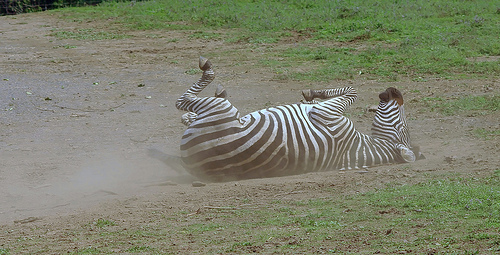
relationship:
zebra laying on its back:
[176, 58, 426, 181] [195, 164, 373, 183]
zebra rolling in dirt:
[176, 58, 426, 181] [1, 1, 498, 254]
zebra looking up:
[176, 58, 426, 181] [0, 0, 497, 96]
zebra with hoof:
[176, 58, 426, 181] [199, 57, 213, 71]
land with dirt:
[0, 2, 498, 254] [1, 1, 498, 254]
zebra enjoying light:
[176, 58, 426, 181] [3, 3, 496, 253]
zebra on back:
[176, 58, 426, 181] [195, 164, 373, 183]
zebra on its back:
[176, 58, 426, 181] [195, 164, 373, 183]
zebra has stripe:
[176, 58, 426, 181] [297, 104, 327, 172]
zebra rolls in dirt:
[176, 58, 426, 181] [1, 1, 498, 254]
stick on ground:
[179, 205, 237, 218] [0, 2, 498, 254]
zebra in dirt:
[176, 58, 426, 181] [1, 1, 498, 254]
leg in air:
[314, 88, 360, 115] [2, 1, 499, 124]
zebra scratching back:
[176, 58, 426, 181] [195, 164, 373, 183]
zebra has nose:
[176, 58, 426, 181] [379, 89, 403, 105]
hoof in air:
[199, 57, 213, 71] [2, 1, 499, 124]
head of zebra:
[371, 87, 423, 165] [176, 58, 426, 181]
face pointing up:
[381, 90, 409, 138] [0, 0, 497, 96]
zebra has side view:
[176, 58, 426, 181] [177, 55, 424, 177]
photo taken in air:
[2, 3, 497, 254] [0, 1, 500, 255]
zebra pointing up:
[176, 58, 426, 181] [0, 0, 497, 96]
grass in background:
[37, 2, 498, 84] [0, 3, 498, 108]